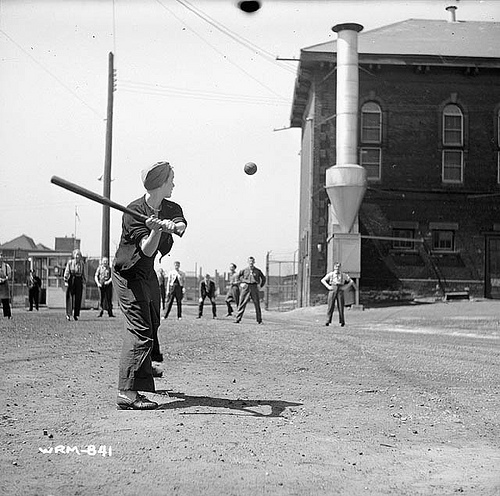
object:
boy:
[109, 152, 187, 410]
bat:
[48, 173, 182, 236]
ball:
[243, 161, 256, 175]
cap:
[140, 159, 176, 188]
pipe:
[323, 20, 369, 311]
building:
[273, 4, 500, 310]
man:
[320, 260, 355, 327]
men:
[0, 252, 267, 325]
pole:
[100, 47, 117, 300]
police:
[25, 272, 43, 310]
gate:
[266, 246, 305, 312]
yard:
[0, 300, 500, 495]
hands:
[144, 213, 179, 234]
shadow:
[155, 386, 305, 420]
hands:
[326, 284, 350, 293]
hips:
[328, 284, 346, 291]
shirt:
[321, 271, 354, 289]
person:
[197, 271, 219, 318]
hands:
[197, 295, 220, 304]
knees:
[197, 294, 216, 305]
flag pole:
[72, 205, 80, 250]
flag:
[78, 211, 81, 221]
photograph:
[0, 0, 500, 495]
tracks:
[301, 325, 498, 449]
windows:
[440, 103, 465, 182]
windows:
[357, 99, 384, 185]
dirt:
[374, 384, 496, 482]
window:
[442, 103, 466, 146]